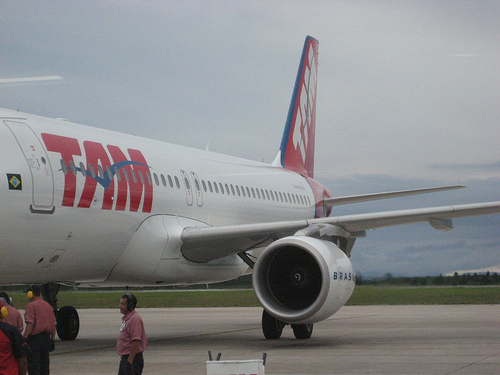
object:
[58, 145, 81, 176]
window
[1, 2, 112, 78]
sky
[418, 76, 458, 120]
cloud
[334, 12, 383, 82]
cloud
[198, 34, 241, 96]
cloud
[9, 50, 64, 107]
cloud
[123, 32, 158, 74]
cloud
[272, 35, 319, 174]
tail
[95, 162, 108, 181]
window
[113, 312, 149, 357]
shirt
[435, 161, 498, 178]
cloud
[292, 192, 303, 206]
window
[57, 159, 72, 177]
window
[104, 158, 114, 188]
window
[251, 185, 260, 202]
window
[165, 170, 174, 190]
window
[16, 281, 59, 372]
man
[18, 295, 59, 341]
shirt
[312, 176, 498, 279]
blue sky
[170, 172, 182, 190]
window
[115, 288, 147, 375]
man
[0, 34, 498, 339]
airplane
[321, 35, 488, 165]
clouds